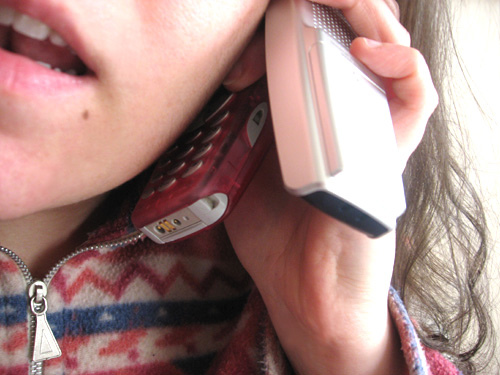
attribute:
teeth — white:
[4, 3, 147, 130]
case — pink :
[133, 73, 275, 244]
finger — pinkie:
[344, 30, 446, 165]